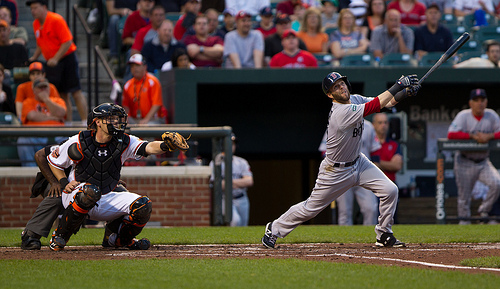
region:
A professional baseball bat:
[405, 30, 470, 90]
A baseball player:
[260, 71, 422, 248]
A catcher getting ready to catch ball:
[47, 101, 189, 252]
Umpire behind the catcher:
[18, 111, 113, 248]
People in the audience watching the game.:
[0, 0, 497, 127]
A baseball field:
[0, 223, 498, 287]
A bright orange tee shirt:
[31, 11, 76, 62]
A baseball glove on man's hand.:
[160, 129, 190, 156]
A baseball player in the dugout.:
[445, 88, 499, 222]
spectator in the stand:
[120, 49, 160, 121]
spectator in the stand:
[266, 23, 317, 67]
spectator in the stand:
[380, 18, 415, 55]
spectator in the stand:
[215, 4, 262, 67]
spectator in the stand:
[372, 5, 404, 59]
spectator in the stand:
[411, 1, 451, 50]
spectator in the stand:
[125, 51, 170, 112]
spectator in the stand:
[14, 78, 69, 123]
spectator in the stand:
[190, 5, 223, 72]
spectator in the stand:
[147, 13, 179, 58]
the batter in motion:
[262, 70, 420, 250]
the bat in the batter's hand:
[408, 32, 468, 92]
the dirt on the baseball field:
[0, 240, 498, 274]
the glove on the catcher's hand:
[161, 130, 191, 152]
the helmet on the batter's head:
[322, 71, 351, 93]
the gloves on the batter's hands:
[387, 74, 420, 101]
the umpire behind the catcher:
[20, 139, 127, 249]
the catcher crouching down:
[45, 103, 191, 250]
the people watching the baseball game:
[1, 0, 498, 224]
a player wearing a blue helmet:
[310, 65, 357, 106]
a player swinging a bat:
[392, 25, 478, 115]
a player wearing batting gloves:
[381, 63, 426, 105]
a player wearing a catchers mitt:
[150, 121, 196, 166]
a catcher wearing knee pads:
[37, 175, 164, 256]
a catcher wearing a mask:
[83, 95, 135, 144]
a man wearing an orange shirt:
[118, 70, 169, 124]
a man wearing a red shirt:
[264, 43, 321, 74]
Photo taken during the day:
[4, 7, 491, 287]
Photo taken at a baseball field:
[9, 12, 486, 281]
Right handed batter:
[256, 56, 455, 252]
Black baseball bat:
[410, 21, 481, 93]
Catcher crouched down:
[27, 95, 197, 252]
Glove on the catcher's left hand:
[156, 123, 187, 160]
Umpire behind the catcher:
[16, 127, 72, 248]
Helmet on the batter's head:
[319, 68, 351, 97]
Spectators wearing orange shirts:
[10, 0, 170, 125]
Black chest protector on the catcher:
[64, 126, 131, 194]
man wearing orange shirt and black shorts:
[27, 4, 88, 128]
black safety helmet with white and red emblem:
[320, 70, 345, 94]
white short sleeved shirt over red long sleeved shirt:
[443, 105, 499, 167]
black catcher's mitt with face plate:
[91, 101, 128, 137]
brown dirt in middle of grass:
[1, 241, 498, 262]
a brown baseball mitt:
[161, 131, 189, 153]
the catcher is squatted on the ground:
[46, 103, 188, 250]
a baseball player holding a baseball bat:
[261, 30, 469, 247]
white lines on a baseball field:
[108, 240, 499, 271]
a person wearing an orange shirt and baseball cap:
[121, 52, 164, 121]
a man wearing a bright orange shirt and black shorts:
[26, 3, 92, 123]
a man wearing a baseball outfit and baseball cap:
[444, 88, 499, 220]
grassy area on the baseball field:
[0, 257, 497, 287]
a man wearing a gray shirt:
[221, 10, 264, 67]